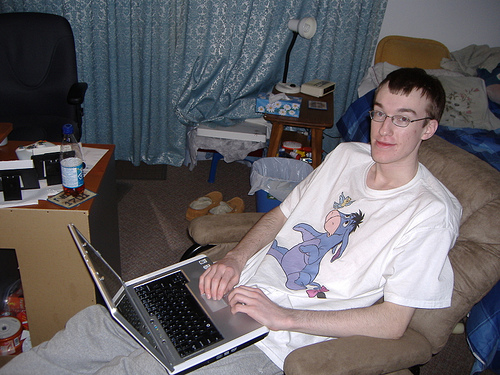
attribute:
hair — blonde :
[356, 62, 453, 142]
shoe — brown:
[190, 189, 215, 225]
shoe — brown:
[217, 199, 250, 216]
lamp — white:
[272, 15, 317, 97]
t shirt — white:
[226, 137, 466, 369]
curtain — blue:
[91, 0, 385, 174]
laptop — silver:
[65, 223, 267, 373]